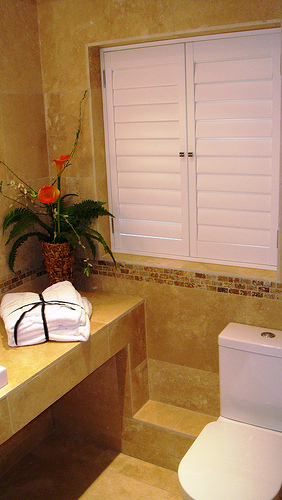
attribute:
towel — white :
[25, 302, 63, 332]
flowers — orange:
[37, 149, 81, 204]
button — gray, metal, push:
[259, 333, 273, 338]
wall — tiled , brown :
[2, 2, 280, 423]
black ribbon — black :
[4, 291, 84, 344]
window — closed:
[90, 45, 250, 223]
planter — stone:
[28, 234, 83, 283]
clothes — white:
[0, 280, 93, 347]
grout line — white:
[106, 324, 111, 357]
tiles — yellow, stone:
[73, 245, 221, 437]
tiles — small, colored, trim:
[99, 253, 272, 310]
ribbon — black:
[8, 288, 76, 342]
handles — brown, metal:
[180, 149, 196, 159]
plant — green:
[1, 157, 117, 280]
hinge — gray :
[98, 67, 108, 89]